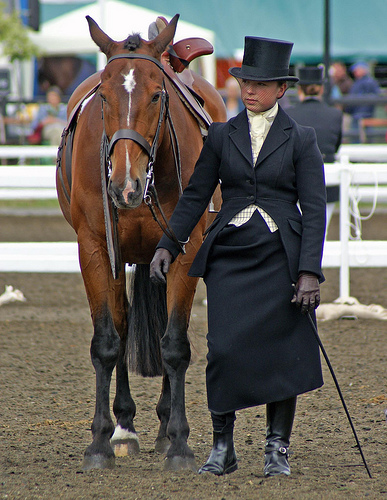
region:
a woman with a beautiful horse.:
[37, 7, 367, 460]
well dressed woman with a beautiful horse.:
[23, 3, 351, 446]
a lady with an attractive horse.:
[21, 4, 353, 418]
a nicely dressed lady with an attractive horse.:
[21, 7, 351, 416]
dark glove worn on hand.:
[290, 269, 327, 323]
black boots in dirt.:
[182, 406, 309, 488]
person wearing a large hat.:
[213, 25, 300, 127]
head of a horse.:
[98, 4, 171, 211]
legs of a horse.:
[77, 318, 197, 481]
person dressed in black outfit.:
[186, 25, 328, 399]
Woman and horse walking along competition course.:
[47, 4, 376, 477]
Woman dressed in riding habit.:
[147, 105, 339, 417]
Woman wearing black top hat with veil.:
[224, 28, 307, 113]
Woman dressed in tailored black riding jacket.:
[155, 108, 339, 278]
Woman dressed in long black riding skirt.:
[197, 220, 356, 420]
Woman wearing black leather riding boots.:
[199, 400, 317, 498]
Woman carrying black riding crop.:
[290, 280, 382, 482]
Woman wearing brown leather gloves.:
[147, 248, 337, 314]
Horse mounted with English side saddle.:
[148, 12, 214, 97]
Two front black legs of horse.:
[79, 303, 195, 484]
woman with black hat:
[229, 32, 300, 82]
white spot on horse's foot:
[109, 423, 139, 442]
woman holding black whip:
[291, 283, 372, 477]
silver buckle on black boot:
[278, 445, 287, 455]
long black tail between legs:
[123, 258, 170, 377]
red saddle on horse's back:
[148, 14, 216, 125]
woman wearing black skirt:
[203, 208, 323, 413]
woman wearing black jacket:
[153, 105, 328, 282]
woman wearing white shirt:
[226, 102, 281, 234]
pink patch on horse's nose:
[119, 179, 134, 206]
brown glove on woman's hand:
[283, 266, 332, 308]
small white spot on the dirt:
[4, 281, 36, 320]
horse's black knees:
[146, 308, 202, 372]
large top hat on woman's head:
[215, 21, 309, 91]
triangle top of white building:
[44, 2, 224, 67]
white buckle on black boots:
[260, 434, 302, 465]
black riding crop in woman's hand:
[287, 277, 374, 497]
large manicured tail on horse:
[110, 237, 178, 391]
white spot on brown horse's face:
[98, 57, 165, 106]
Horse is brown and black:
[40, 2, 236, 477]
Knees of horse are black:
[69, 317, 200, 385]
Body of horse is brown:
[30, 6, 237, 310]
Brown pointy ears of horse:
[65, 4, 185, 55]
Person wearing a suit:
[133, 12, 382, 496]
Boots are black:
[190, 394, 318, 483]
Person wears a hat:
[133, 22, 338, 488]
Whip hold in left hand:
[284, 280, 384, 484]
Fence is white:
[0, 122, 385, 324]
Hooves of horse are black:
[66, 448, 200, 485]